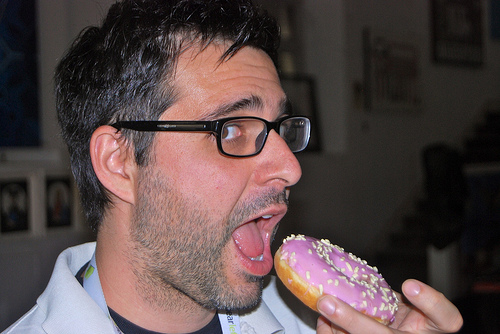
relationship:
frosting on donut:
[288, 233, 399, 317] [268, 225, 398, 325]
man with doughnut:
[60, 38, 323, 322] [253, 223, 415, 316]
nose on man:
[253, 134, 303, 188] [1, 0, 466, 333]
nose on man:
[253, 134, 303, 188] [24, 12, 417, 330]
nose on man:
[253, 143, 310, 193] [32, 4, 342, 323]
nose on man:
[253, 134, 303, 188] [42, 14, 322, 329]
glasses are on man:
[108, 107, 319, 157] [44, 10, 396, 331]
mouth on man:
[227, 198, 292, 282] [32, 4, 342, 323]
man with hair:
[1, 0, 466, 333] [55, 7, 282, 165]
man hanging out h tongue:
[1, 0, 466, 333] [232, 222, 268, 265]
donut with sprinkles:
[270, 233, 401, 332] [286, 240, 404, 316]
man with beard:
[1, 0, 466, 333] [130, 149, 280, 303]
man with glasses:
[1, 0, 466, 333] [86, 104, 324, 167]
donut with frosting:
[270, 229, 402, 332] [281, 227, 410, 327]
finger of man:
[401, 280, 461, 332] [1, 0, 466, 333]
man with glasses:
[1, 0, 466, 333] [101, 109, 317, 161]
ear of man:
[84, 125, 133, 205] [1, 0, 466, 333]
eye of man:
[208, 118, 257, 143] [1, 0, 466, 333]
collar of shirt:
[8, 227, 331, 332] [39, 240, 277, 332]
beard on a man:
[130, 165, 288, 308] [1, 0, 466, 333]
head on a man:
[62, 9, 298, 310] [1, 0, 466, 333]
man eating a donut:
[1, 0, 466, 333] [273, 233, 409, 331]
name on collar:
[217, 307, 251, 330] [34, 241, 286, 333]